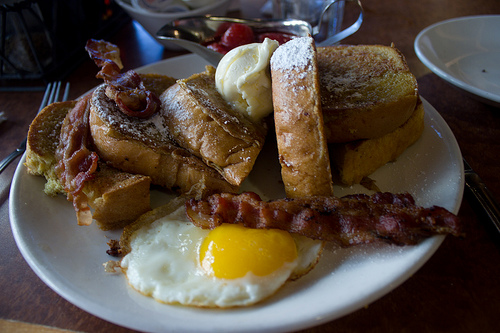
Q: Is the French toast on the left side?
A: Yes, the French toast is on the left of the image.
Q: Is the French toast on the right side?
A: No, the French toast is on the left of the image.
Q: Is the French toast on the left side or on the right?
A: The French toast is on the left of the image.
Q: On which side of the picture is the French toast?
A: The French toast is on the left of the image.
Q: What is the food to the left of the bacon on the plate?
A: The food is a French toast.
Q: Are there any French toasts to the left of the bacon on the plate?
A: Yes, there is a French toast to the left of the bacon.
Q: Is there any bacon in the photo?
A: Yes, there is bacon.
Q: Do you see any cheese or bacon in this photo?
A: Yes, there is bacon.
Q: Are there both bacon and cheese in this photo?
A: No, there is bacon but no cheese.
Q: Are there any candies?
A: No, there are no candies.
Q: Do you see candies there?
A: No, there are no candies.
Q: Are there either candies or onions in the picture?
A: No, there are no candies or onions.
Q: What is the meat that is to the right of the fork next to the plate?
A: The meat is bacon.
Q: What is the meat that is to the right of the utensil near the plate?
A: The meat is bacon.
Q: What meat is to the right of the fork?
A: The meat is bacon.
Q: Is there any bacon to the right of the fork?
A: Yes, there is bacon to the right of the fork.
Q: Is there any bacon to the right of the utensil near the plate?
A: Yes, there is bacon to the right of the fork.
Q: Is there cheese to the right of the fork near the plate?
A: No, there is bacon to the right of the fork.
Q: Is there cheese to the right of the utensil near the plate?
A: No, there is bacon to the right of the fork.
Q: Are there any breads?
A: Yes, there is a bread.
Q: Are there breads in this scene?
A: Yes, there is a bread.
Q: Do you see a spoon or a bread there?
A: Yes, there is a bread.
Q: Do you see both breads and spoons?
A: No, there is a bread but no spoons.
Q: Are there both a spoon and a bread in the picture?
A: No, there is a bread but no spoons.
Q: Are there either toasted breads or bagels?
A: Yes, there is a toasted bread.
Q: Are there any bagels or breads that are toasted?
A: Yes, the bread is toasted.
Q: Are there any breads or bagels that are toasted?
A: Yes, the bread is toasted.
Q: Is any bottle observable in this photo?
A: No, there are no bottles.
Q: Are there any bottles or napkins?
A: No, there are no bottles or napkins.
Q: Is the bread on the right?
A: Yes, the bread is on the right of the image.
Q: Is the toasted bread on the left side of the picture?
A: No, the bread is on the right of the image.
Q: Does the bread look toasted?
A: Yes, the bread is toasted.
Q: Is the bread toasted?
A: Yes, the bread is toasted.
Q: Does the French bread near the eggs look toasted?
A: Yes, the bread is toasted.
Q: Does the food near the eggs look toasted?
A: Yes, the bread is toasted.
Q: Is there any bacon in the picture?
A: Yes, there is bacon.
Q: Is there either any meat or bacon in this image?
A: Yes, there is bacon.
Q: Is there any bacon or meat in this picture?
A: Yes, there is bacon.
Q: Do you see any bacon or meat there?
A: Yes, there is bacon.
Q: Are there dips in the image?
A: No, there are no dips.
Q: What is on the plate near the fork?
A: The bacon is on the plate.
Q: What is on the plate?
A: The bacon is on the plate.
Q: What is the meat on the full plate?
A: The meat is bacon.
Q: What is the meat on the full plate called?
A: The meat is bacon.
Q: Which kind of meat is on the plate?
A: The meat is bacon.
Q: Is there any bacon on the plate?
A: Yes, there is bacon on the plate.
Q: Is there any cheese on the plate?
A: No, there is bacon on the plate.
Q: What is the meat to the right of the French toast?
A: The meat is bacon.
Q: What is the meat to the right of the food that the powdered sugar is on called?
A: The meat is bacon.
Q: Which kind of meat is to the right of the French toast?
A: The meat is bacon.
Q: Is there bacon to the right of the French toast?
A: Yes, there is bacon to the right of the French toast.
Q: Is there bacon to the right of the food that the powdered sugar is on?
A: Yes, there is bacon to the right of the French toast.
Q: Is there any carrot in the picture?
A: No, there are no carrots.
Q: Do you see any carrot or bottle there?
A: No, there are no carrots or bottles.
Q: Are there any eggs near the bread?
A: Yes, there are eggs near the bread.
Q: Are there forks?
A: Yes, there is a fork.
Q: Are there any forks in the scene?
A: Yes, there is a fork.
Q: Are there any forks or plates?
A: Yes, there is a fork.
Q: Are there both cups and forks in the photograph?
A: No, there is a fork but no cups.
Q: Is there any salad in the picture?
A: No, there is no salad.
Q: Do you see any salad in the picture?
A: No, there is no salad.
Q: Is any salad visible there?
A: No, there is no salad.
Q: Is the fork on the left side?
A: Yes, the fork is on the left of the image.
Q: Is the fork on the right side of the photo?
A: No, the fork is on the left of the image.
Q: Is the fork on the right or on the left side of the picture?
A: The fork is on the left of the image.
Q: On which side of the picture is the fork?
A: The fork is on the left of the image.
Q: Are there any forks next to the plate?
A: Yes, there is a fork next to the plate.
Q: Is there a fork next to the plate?
A: Yes, there is a fork next to the plate.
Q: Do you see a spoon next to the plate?
A: No, there is a fork next to the plate.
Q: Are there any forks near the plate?
A: Yes, there is a fork near the plate.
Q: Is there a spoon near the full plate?
A: No, there is a fork near the plate.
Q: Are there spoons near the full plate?
A: No, there is a fork near the plate.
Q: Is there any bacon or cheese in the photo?
A: Yes, there is bacon.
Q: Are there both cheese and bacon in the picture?
A: No, there is bacon but no cheese.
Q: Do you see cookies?
A: No, there are no cookies.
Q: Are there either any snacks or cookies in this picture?
A: No, there are no cookies or snacks.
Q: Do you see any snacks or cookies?
A: No, there are no cookies or snacks.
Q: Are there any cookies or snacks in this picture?
A: No, there are no cookies or snacks.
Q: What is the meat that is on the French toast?
A: The meat is bacon.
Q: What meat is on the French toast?
A: The meat is bacon.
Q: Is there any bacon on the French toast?
A: Yes, there is bacon on the French toast.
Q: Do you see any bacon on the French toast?
A: Yes, there is bacon on the French toast.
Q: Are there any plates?
A: Yes, there is a plate.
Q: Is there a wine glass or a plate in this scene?
A: Yes, there is a plate.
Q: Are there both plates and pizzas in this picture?
A: No, there is a plate but no pizzas.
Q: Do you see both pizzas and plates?
A: No, there is a plate but no pizzas.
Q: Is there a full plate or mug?
A: Yes, there is a full plate.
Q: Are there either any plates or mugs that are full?
A: Yes, the plate is full.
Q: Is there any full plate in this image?
A: Yes, there is a full plate.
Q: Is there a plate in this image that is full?
A: Yes, there is a plate that is full.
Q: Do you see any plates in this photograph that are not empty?
A: Yes, there is an full plate.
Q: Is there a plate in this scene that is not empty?
A: Yes, there is an full plate.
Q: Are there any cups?
A: No, there are no cups.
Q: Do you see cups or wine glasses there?
A: No, there are no cups or wine glasses.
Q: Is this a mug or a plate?
A: This is a plate.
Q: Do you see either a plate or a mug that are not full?
A: No, there is a plate but it is full.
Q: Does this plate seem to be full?
A: Yes, the plate is full.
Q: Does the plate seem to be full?
A: Yes, the plate is full.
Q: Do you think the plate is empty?
A: No, the plate is full.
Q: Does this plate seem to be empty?
A: No, the plate is full.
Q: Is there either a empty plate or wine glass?
A: No, there is a plate but it is full.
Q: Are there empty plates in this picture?
A: No, there is a plate but it is full.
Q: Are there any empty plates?
A: No, there is a plate but it is full.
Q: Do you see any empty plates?
A: No, there is a plate but it is full.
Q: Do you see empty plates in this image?
A: No, there is a plate but it is full.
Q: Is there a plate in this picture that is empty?
A: No, there is a plate but it is full.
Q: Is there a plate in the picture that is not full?
A: No, there is a plate but it is full.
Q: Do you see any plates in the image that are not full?
A: No, there is a plate but it is full.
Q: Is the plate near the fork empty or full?
A: The plate is full.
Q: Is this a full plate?
A: Yes, this is a full plate.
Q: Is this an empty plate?
A: No, this is a full plate.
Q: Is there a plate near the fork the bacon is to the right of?
A: Yes, there is a plate near the fork.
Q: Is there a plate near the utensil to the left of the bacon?
A: Yes, there is a plate near the fork.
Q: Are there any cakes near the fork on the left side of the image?
A: No, there is a plate near the fork.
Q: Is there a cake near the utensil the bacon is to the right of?
A: No, there is a plate near the fork.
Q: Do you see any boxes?
A: No, there are no boxes.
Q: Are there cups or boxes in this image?
A: No, there are no boxes or cups.